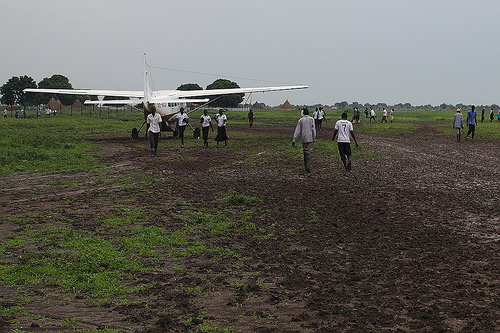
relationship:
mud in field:
[104, 124, 500, 332] [0, 112, 498, 331]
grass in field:
[1, 112, 499, 203] [0, 112, 498, 331]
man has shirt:
[331, 112, 360, 172] [334, 118, 354, 143]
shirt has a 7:
[334, 118, 354, 143] [343, 122, 348, 133]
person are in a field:
[453, 107, 464, 141] [0, 112, 498, 331]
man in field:
[331, 112, 360, 172] [0, 112, 498, 331]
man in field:
[290, 107, 319, 171] [0, 112, 498, 331]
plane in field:
[22, 50, 310, 135] [0, 112, 498, 331]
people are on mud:
[144, 105, 500, 174] [104, 124, 500, 332]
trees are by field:
[1, 73, 246, 110] [0, 112, 498, 331]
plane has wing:
[22, 50, 310, 135] [22, 85, 146, 101]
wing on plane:
[22, 85, 146, 101] [22, 50, 310, 135]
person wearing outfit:
[453, 107, 463, 141] [453, 108, 464, 134]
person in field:
[144, 107, 161, 154] [0, 112, 498, 331]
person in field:
[290, 107, 319, 171] [0, 112, 498, 331]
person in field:
[453, 107, 463, 141] [0, 112, 498, 331]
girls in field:
[214, 109, 230, 148] [0, 112, 498, 331]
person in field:
[467, 102, 478, 140] [0, 112, 498, 331]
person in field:
[246, 104, 254, 127] [0, 112, 498, 331]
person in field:
[387, 106, 397, 124] [0, 112, 498, 331]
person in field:
[318, 107, 325, 127] [0, 112, 498, 331]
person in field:
[370, 107, 378, 123] [0, 112, 498, 331]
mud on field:
[104, 124, 500, 332] [0, 111, 497, 331]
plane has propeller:
[22, 50, 310, 135] [141, 97, 155, 116]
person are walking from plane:
[144, 107, 164, 154] [22, 50, 310, 135]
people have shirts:
[144, 105, 500, 174] [145, 113, 364, 144]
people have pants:
[144, 105, 500, 174] [145, 118, 366, 160]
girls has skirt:
[214, 109, 230, 148] [214, 123, 227, 143]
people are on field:
[144, 105, 500, 174] [0, 112, 498, 331]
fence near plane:
[0, 102, 142, 121] [22, 50, 310, 135]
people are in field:
[144, 105, 500, 174] [0, 112, 498, 331]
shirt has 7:
[334, 118, 354, 143] [343, 122, 348, 133]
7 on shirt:
[343, 122, 348, 133] [334, 118, 354, 143]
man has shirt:
[467, 102, 478, 140] [467, 110, 478, 126]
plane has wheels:
[22, 50, 310, 135] [132, 127, 201, 138]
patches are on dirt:
[0, 167, 310, 331] [104, 124, 500, 332]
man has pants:
[290, 107, 319, 171] [300, 141, 314, 172]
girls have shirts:
[175, 108, 232, 148] [176, 110, 229, 128]